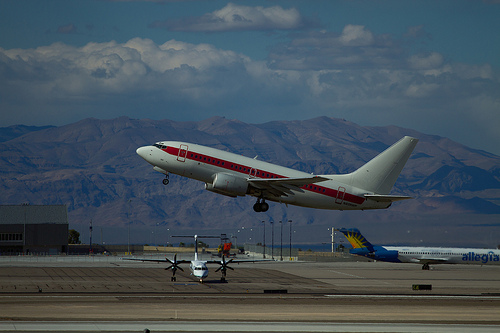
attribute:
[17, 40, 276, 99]
clouds — White 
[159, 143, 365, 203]
stripe — red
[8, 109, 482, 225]
mountains — rising, background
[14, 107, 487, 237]
hill — background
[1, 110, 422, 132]
montian tops — brown 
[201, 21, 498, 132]
sky — blue 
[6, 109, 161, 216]
mountains — hilly 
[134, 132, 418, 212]
plane — red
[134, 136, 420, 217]
plane — taking off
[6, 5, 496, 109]
clouds — White 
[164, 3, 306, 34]
cloud — White 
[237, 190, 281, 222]
tires — back tires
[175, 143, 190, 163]
door — passenger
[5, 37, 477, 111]
clouds — White 